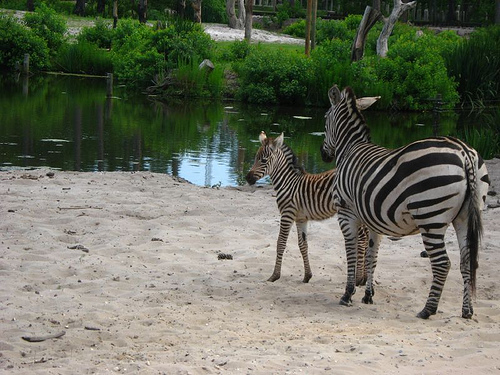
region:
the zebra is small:
[240, 123, 322, 273]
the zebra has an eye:
[255, 153, 275, 170]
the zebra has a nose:
[242, 165, 259, 190]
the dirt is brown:
[107, 248, 184, 348]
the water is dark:
[65, 105, 182, 160]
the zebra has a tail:
[450, 143, 487, 294]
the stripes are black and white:
[377, 167, 434, 207]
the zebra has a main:
[348, 94, 367, 136]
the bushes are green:
[305, 34, 437, 86]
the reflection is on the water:
[190, 136, 236, 186]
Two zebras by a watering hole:
[250, 86, 484, 320]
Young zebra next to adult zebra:
[246, 135, 364, 280]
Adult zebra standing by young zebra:
[315, 85, 492, 315]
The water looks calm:
[12, 85, 234, 188]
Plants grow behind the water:
[6, 11, 451, 98]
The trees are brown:
[351, 3, 401, 60]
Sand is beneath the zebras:
[15, 280, 454, 366]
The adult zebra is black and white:
[319, 90, 483, 309]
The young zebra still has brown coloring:
[245, 130, 360, 281]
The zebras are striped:
[221, 87, 492, 322]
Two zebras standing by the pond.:
[235, 84, 467, 294]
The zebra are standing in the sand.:
[313, 109, 499, 315]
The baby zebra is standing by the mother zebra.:
[243, 97, 451, 299]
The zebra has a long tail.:
[465, 168, 490, 288]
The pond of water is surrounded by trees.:
[91, 16, 347, 109]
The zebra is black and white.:
[326, 77, 471, 292]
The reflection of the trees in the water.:
[95, 85, 255, 170]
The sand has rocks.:
[72, 227, 244, 343]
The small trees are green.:
[87, 17, 234, 90]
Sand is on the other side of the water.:
[206, 18, 293, 43]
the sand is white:
[167, 310, 201, 370]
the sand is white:
[178, 319, 206, 337]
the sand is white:
[213, 317, 268, 366]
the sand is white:
[210, 252, 317, 343]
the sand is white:
[213, 282, 268, 339]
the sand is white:
[243, 291, 324, 373]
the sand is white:
[255, 340, 290, 365]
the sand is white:
[161, 244, 298, 366]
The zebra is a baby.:
[221, 121, 341, 303]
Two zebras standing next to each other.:
[220, 58, 485, 329]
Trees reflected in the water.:
[23, 95, 176, 150]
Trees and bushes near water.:
[65, 0, 330, 68]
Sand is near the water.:
[21, 206, 248, 356]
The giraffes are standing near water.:
[155, 50, 491, 341]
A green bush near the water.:
[367, 28, 477, 134]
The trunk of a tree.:
[230, 2, 270, 42]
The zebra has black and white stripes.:
[356, 158, 451, 195]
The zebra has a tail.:
[438, 137, 498, 289]